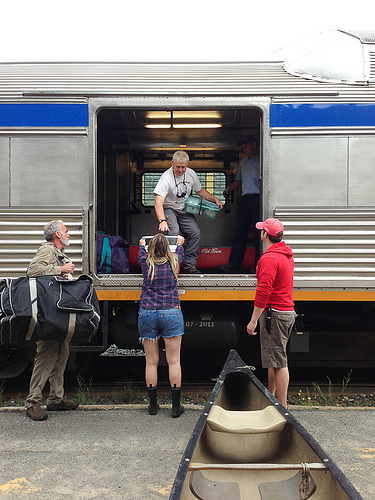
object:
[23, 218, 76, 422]
man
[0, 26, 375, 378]
train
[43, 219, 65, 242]
hair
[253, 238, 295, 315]
coat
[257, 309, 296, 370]
short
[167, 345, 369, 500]
boat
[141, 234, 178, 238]
trim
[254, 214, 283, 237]
cap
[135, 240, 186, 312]
shirt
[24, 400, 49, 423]
shoe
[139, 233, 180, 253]
container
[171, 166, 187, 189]
strap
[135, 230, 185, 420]
lady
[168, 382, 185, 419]
boot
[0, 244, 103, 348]
bag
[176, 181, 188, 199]
glass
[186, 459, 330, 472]
rope